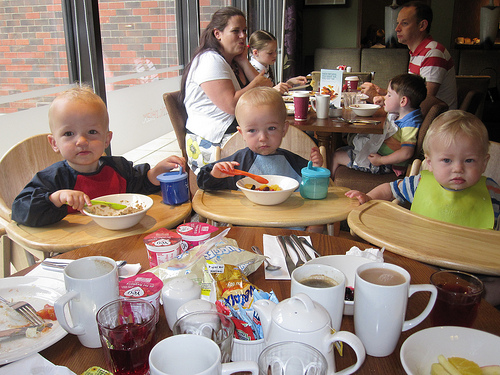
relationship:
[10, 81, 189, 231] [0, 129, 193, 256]
baby sitting in high chair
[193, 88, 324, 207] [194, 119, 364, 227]
baby sitting in high chair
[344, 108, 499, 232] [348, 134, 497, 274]
baby sitting in high chair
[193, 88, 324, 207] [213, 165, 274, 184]
baby holding spoon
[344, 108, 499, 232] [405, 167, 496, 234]
baby wearing bib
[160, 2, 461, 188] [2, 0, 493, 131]
family sitting in background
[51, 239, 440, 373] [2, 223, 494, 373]
cups on table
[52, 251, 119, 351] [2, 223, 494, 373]
cup on table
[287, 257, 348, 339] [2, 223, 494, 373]
cup on table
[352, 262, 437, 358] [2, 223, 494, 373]
cup on table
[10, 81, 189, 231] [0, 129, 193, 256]
baby in high chair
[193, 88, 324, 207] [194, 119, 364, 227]
baby in high chair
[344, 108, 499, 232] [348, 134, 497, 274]
baby in high chair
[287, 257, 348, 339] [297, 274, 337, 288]
cup has coffee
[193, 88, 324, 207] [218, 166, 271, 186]
baby holding spoon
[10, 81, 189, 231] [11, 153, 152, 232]
baby wearing top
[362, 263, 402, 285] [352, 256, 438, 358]
hot chocolate in cup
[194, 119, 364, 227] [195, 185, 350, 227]
high chair has part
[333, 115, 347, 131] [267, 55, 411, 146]
part of table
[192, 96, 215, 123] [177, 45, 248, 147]
part of sweater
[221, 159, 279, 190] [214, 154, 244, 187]
spoon in hand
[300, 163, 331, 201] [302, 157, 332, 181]
cup with lid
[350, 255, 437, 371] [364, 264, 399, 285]
cup of coffee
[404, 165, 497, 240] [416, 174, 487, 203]
bib around neck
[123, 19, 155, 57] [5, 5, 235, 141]
bricks on wall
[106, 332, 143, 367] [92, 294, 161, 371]
liquid in glass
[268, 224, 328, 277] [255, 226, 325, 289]
silverware on napkin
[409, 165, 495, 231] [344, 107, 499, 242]
bib on baby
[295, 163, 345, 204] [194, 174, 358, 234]
cup on tray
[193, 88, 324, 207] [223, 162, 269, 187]
baby holding spoon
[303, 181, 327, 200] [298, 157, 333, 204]
milk in cup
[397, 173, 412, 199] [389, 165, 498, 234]
stripe on shirt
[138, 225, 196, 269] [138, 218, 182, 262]
cereal in cup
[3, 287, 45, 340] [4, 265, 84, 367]
fork laying on plate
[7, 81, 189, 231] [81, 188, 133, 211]
baby holding spoon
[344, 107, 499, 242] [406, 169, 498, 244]
baby wearing bib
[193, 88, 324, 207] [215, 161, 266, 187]
baby has spoon